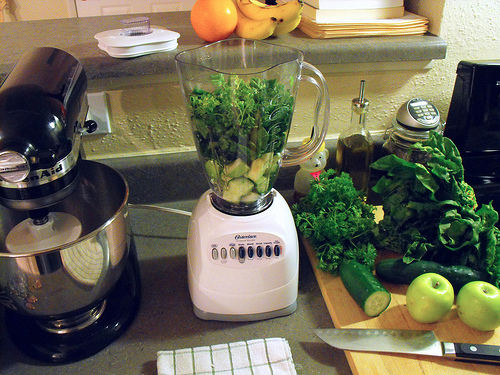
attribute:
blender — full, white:
[175, 33, 335, 327]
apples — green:
[402, 269, 499, 335]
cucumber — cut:
[340, 256, 395, 320]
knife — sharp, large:
[309, 321, 499, 369]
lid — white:
[96, 15, 186, 64]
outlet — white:
[81, 90, 123, 139]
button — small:
[273, 244, 283, 259]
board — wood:
[302, 191, 499, 369]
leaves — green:
[294, 161, 395, 275]